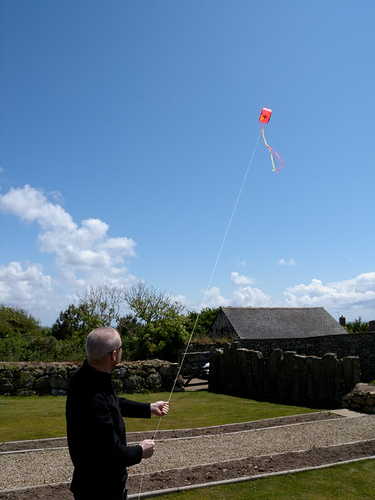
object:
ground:
[0, 413, 374, 499]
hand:
[151, 400, 169, 416]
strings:
[259, 121, 286, 175]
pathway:
[0, 411, 375, 492]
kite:
[259, 107, 285, 174]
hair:
[85, 326, 122, 366]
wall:
[208, 340, 360, 412]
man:
[63, 326, 170, 500]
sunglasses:
[107, 343, 125, 354]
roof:
[207, 306, 350, 344]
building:
[208, 306, 349, 382]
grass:
[169, 387, 260, 427]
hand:
[139, 438, 156, 459]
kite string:
[140, 132, 263, 483]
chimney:
[339, 314, 346, 326]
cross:
[263, 113, 267, 120]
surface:
[0, 384, 326, 437]